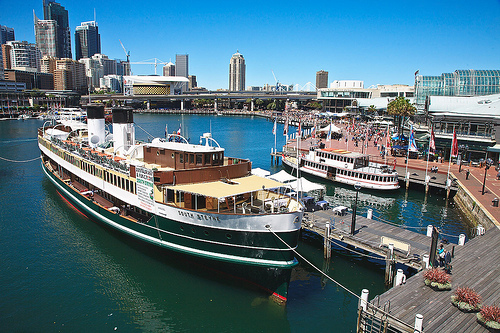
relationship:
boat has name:
[39, 105, 299, 276] [176, 208, 222, 222]